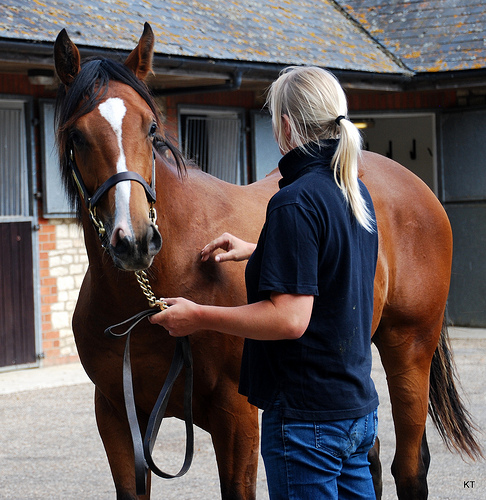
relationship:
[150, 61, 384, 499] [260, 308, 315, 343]
lady has an elbow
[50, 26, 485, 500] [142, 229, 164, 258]
horse has a nostril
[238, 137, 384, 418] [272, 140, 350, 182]
shirt has a collar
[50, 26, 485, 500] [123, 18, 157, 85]
horse has an ear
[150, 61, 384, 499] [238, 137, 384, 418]
lady wearing a shirt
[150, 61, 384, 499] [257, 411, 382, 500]
lady wearing jeans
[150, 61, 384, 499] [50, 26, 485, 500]
lady standing near a horse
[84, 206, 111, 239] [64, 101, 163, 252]
metal accents on bridle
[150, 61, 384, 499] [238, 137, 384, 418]
lady wearing a polo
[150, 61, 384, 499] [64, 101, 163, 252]
lady holding bridle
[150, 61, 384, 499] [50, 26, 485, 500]
lady petting horse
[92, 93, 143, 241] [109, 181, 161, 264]
stripe on nose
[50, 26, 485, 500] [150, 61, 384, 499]
horse taller than lady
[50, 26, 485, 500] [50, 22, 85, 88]
horse has a pointed ear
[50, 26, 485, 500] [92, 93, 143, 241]
horse has a blaze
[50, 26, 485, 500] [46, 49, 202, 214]
horse has a mane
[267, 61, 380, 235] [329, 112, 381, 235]
hair in a ponytail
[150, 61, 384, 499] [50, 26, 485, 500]
lady prepares to ride horse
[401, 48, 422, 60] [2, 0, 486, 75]
spot on roof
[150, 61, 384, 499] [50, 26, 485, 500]
lady next to horse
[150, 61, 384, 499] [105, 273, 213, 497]
lady holding leash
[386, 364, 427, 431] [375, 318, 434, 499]
veins are showing in leg